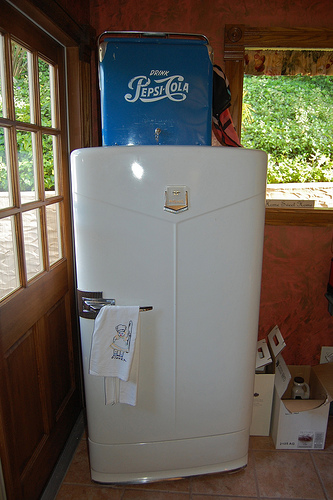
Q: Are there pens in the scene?
A: No, there are no pens.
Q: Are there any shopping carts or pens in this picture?
A: No, there are no pens or shopping carts.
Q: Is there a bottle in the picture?
A: Yes, there is a bottle.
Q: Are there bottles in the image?
A: Yes, there is a bottle.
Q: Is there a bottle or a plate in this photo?
A: Yes, there is a bottle.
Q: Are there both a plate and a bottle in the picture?
A: No, there is a bottle but no plates.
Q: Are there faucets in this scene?
A: No, there are no faucets.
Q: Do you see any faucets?
A: No, there are no faucets.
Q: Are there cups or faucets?
A: No, there are no faucets or cups.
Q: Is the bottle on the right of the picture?
A: Yes, the bottle is on the right of the image.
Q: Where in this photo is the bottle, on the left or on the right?
A: The bottle is on the right of the image.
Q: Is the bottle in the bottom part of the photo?
A: Yes, the bottle is in the bottom of the image.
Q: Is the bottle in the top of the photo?
A: No, the bottle is in the bottom of the image.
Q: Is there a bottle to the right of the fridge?
A: Yes, there is a bottle to the right of the fridge.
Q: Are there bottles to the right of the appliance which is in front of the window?
A: Yes, there is a bottle to the right of the fridge.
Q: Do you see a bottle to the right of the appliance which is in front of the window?
A: Yes, there is a bottle to the right of the fridge.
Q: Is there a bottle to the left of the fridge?
A: No, the bottle is to the right of the fridge.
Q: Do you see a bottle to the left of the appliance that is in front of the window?
A: No, the bottle is to the right of the fridge.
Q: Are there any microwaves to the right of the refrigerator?
A: No, there is a bottle to the right of the refrigerator.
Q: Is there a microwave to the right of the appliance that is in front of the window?
A: No, there is a bottle to the right of the refrigerator.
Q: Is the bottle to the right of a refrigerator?
A: Yes, the bottle is to the right of a refrigerator.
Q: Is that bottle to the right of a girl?
A: No, the bottle is to the right of a refrigerator.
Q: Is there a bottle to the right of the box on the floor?
A: Yes, there is a bottle to the right of the box.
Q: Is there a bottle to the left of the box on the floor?
A: No, the bottle is to the right of the box.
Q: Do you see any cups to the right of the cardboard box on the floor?
A: No, there is a bottle to the right of the box.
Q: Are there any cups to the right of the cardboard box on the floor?
A: No, there is a bottle to the right of the box.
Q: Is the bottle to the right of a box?
A: Yes, the bottle is to the right of a box.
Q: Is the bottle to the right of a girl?
A: No, the bottle is to the right of a box.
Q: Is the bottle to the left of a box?
A: No, the bottle is to the right of a box.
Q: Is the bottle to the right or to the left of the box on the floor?
A: The bottle is to the right of the box.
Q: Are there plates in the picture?
A: No, there are no plates.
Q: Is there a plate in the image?
A: No, there are no plates.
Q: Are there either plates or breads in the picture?
A: No, there are no plates or breads.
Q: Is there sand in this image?
A: Yes, there is sand.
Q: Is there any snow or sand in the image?
A: Yes, there is sand.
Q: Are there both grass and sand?
A: No, there is sand but no grass.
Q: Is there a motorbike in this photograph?
A: No, there are no motorcycles.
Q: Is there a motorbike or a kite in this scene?
A: No, there are no motorcycles or kites.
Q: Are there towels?
A: Yes, there is a towel.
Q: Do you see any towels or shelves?
A: Yes, there is a towel.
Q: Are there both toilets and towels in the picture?
A: No, there is a towel but no toilets.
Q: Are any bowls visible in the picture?
A: No, there are no bowls.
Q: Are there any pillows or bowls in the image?
A: No, there are no bowls or pillows.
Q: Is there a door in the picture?
A: Yes, there is a door.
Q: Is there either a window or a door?
A: Yes, there is a door.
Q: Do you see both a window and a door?
A: Yes, there are both a door and a window.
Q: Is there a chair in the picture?
A: No, there are no chairs.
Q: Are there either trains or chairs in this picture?
A: No, there are no chairs or trains.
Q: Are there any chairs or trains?
A: No, there are no chairs or trains.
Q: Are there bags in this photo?
A: No, there are no bags.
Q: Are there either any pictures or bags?
A: No, there are no bags or pictures.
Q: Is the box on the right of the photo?
A: Yes, the box is on the right of the image.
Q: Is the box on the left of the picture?
A: No, the box is on the right of the image.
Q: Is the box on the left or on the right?
A: The box is on the right of the image.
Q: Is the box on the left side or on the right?
A: The box is on the right of the image.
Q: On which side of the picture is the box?
A: The box is on the right of the image.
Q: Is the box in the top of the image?
A: No, the box is in the bottom of the image.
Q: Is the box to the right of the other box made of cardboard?
A: Yes, the box is made of cardboard.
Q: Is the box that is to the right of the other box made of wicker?
A: No, the box is made of cardboard.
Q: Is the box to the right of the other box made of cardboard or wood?
A: The box is made of cardboard.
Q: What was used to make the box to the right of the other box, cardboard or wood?
A: The box is made of cardboard.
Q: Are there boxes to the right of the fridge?
A: Yes, there is a box to the right of the fridge.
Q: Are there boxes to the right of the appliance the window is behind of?
A: Yes, there is a box to the right of the fridge.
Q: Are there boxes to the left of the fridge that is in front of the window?
A: No, the box is to the right of the freezer.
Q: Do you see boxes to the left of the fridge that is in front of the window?
A: No, the box is to the right of the freezer.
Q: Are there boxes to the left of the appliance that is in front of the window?
A: No, the box is to the right of the freezer.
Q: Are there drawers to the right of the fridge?
A: No, there is a box to the right of the fridge.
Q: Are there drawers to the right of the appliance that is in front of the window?
A: No, there is a box to the right of the fridge.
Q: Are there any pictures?
A: No, there are no pictures.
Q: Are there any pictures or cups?
A: No, there are no pictures or cups.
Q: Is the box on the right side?
A: Yes, the box is on the right of the image.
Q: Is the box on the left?
A: No, the box is on the right of the image.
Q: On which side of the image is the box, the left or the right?
A: The box is on the right of the image.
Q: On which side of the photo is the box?
A: The box is on the right of the image.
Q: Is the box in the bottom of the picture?
A: Yes, the box is in the bottom of the image.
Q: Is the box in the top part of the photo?
A: No, the box is in the bottom of the image.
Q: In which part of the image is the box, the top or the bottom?
A: The box is in the bottom of the image.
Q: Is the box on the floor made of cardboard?
A: Yes, the box is made of cardboard.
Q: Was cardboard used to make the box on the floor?
A: Yes, the box is made of cardboard.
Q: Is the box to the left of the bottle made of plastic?
A: No, the box is made of cardboard.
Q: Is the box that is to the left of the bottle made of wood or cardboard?
A: The box is made of cardboard.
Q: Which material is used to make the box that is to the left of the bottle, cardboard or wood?
A: The box is made of cardboard.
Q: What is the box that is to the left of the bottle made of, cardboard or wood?
A: The box is made of cardboard.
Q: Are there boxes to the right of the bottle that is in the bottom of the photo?
A: No, the box is to the left of the bottle.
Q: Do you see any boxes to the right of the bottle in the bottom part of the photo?
A: No, the box is to the left of the bottle.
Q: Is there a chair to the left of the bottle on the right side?
A: No, there is a box to the left of the bottle.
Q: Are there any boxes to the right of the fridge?
A: Yes, there is a box to the right of the fridge.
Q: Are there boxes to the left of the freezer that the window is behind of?
A: No, the box is to the right of the freezer.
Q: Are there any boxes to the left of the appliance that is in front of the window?
A: No, the box is to the right of the freezer.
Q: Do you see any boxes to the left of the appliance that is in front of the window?
A: No, the box is to the right of the freezer.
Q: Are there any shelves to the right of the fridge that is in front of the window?
A: No, there is a box to the right of the fridge.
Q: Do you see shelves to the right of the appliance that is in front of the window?
A: No, there is a box to the right of the fridge.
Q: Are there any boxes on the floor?
A: Yes, there is a box on the floor.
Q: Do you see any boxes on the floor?
A: Yes, there is a box on the floor.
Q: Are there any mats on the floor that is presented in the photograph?
A: No, there is a box on the floor.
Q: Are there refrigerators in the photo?
A: Yes, there is a refrigerator.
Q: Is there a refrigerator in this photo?
A: Yes, there is a refrigerator.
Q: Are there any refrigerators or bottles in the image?
A: Yes, there is a refrigerator.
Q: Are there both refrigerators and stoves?
A: No, there is a refrigerator but no stoves.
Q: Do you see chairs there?
A: No, there are no chairs.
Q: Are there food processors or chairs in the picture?
A: No, there are no chairs or food processors.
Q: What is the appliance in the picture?
A: The appliance is a refrigerator.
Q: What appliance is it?
A: The appliance is a refrigerator.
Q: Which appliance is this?
A: This is a refrigerator.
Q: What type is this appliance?
A: This is a refrigerator.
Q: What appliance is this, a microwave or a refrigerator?
A: This is a refrigerator.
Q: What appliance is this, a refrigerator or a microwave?
A: This is a refrigerator.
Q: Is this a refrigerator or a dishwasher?
A: This is a refrigerator.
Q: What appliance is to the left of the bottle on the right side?
A: The appliance is a refrigerator.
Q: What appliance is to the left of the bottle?
A: The appliance is a refrigerator.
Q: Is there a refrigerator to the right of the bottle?
A: No, the refrigerator is to the left of the bottle.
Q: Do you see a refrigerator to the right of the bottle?
A: No, the refrigerator is to the left of the bottle.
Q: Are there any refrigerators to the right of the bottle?
A: No, the refrigerator is to the left of the bottle.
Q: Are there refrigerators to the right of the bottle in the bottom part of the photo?
A: No, the refrigerator is to the left of the bottle.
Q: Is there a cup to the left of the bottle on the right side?
A: No, there is a refrigerator to the left of the bottle.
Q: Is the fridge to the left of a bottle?
A: Yes, the fridge is to the left of a bottle.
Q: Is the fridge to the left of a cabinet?
A: No, the fridge is to the left of a bottle.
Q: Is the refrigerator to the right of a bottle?
A: No, the refrigerator is to the left of a bottle.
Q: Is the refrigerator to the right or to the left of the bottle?
A: The refrigerator is to the left of the bottle.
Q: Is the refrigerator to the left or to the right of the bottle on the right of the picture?
A: The refrigerator is to the left of the bottle.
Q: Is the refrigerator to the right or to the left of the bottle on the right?
A: The refrigerator is to the left of the bottle.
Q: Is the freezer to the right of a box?
A: No, the freezer is to the left of a box.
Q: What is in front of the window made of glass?
A: The freezer is in front of the window.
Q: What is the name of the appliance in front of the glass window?
A: The appliance is a refrigerator.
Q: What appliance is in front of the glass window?
A: The appliance is a refrigerator.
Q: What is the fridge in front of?
A: The fridge is in front of the window.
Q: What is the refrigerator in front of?
A: The fridge is in front of the window.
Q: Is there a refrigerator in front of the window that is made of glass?
A: Yes, there is a refrigerator in front of the window.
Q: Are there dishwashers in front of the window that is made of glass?
A: No, there is a refrigerator in front of the window.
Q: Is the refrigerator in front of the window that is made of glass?
A: Yes, the refrigerator is in front of the window.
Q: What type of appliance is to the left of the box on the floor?
A: The appliance is a refrigerator.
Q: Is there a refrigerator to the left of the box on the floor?
A: Yes, there is a refrigerator to the left of the box.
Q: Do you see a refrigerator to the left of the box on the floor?
A: Yes, there is a refrigerator to the left of the box.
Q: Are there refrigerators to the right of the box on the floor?
A: No, the refrigerator is to the left of the box.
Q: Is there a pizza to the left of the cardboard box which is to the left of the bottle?
A: No, there is a refrigerator to the left of the box.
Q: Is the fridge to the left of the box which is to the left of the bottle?
A: Yes, the fridge is to the left of the box.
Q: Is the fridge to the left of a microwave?
A: No, the fridge is to the left of the box.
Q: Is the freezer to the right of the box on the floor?
A: No, the freezer is to the left of the box.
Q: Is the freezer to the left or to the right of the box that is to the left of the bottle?
A: The freezer is to the left of the box.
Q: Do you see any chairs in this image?
A: No, there are no chairs.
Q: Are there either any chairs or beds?
A: No, there are no chairs or beds.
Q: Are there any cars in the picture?
A: No, there are no cars.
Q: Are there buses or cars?
A: No, there are no cars or buses.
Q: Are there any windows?
A: Yes, there is a window.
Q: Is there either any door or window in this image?
A: Yes, there is a window.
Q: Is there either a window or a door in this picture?
A: Yes, there is a window.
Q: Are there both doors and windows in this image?
A: Yes, there are both a window and a door.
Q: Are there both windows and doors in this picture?
A: Yes, there are both a window and a door.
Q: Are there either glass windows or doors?
A: Yes, there is a glass window.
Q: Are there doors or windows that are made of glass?
A: Yes, the window is made of glass.